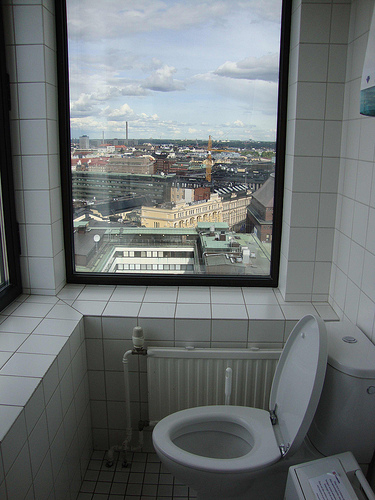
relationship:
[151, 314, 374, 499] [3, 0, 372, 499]
toilet in bathroom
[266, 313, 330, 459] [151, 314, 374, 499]
lid on toilet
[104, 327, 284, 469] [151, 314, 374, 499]
radiator near toilet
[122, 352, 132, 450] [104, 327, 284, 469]
pipe on radiator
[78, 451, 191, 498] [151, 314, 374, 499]
tile near toilet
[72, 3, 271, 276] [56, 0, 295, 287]
window has a frame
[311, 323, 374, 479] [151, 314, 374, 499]
tank on toilet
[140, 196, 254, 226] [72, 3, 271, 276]
building outside of window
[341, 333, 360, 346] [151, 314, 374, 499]
flush on top of toilet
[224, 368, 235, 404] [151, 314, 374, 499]
brush for cleaning toilet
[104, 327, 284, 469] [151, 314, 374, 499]
radiator next to toilet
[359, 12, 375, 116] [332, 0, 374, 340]
air refreshener on wall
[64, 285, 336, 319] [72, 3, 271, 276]
sill along window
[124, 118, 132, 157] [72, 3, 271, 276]
building outside of window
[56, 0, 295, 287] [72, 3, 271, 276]
frame around window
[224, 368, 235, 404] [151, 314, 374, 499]
brush near toilet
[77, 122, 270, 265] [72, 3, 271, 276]
city outside of window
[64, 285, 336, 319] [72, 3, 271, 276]
sill under window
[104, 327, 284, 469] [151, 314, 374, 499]
radiator behind toilet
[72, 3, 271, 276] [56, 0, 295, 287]
window has frame